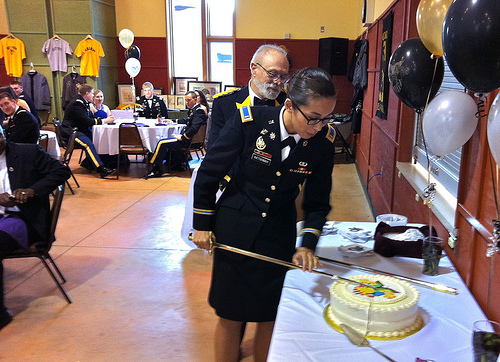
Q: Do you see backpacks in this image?
A: Yes, there is a backpack.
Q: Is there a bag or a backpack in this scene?
A: Yes, there is a backpack.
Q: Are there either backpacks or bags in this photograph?
A: Yes, there is a backpack.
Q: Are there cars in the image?
A: No, there are no cars.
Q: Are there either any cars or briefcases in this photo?
A: No, there are no cars or briefcases.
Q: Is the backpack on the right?
A: Yes, the backpack is on the right of the image.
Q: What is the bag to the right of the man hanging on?
A: The backpack is hanging on the wall.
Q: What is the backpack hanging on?
A: The backpack is hanging on the wall.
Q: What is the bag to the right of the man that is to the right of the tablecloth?
A: The bag is a backpack.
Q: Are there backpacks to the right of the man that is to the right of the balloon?
A: Yes, there is a backpack to the right of the man.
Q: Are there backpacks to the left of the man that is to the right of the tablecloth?
A: No, the backpack is to the right of the man.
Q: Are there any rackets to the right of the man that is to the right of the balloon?
A: No, there is a backpack to the right of the man.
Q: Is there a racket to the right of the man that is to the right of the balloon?
A: No, there is a backpack to the right of the man.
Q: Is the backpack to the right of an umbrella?
A: No, the backpack is to the right of the man.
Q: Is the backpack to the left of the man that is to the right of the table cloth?
A: No, the backpack is to the right of the man.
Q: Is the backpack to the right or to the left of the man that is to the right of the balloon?
A: The backpack is to the right of the man.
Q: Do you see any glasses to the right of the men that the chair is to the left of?
A: Yes, there are glasses to the right of the men.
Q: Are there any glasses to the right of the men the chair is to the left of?
A: Yes, there are glasses to the right of the men.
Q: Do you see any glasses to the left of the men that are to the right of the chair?
A: No, the glasses are to the right of the men.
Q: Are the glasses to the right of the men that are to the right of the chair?
A: Yes, the glasses are to the right of the men.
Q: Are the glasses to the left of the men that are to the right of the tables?
A: No, the glasses are to the right of the men.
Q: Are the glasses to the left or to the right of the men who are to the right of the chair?
A: The glasses are to the right of the men.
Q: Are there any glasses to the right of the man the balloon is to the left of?
A: Yes, there are glasses to the right of the man.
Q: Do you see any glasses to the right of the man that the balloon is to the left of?
A: Yes, there are glasses to the right of the man.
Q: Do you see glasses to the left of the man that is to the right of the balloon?
A: No, the glasses are to the right of the man.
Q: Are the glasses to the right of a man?
A: Yes, the glasses are to the right of a man.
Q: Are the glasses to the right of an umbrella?
A: No, the glasses are to the right of a man.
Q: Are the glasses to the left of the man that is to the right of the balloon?
A: No, the glasses are to the right of the man.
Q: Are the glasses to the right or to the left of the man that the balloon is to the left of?
A: The glasses are to the right of the man.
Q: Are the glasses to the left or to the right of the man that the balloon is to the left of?
A: The glasses are to the right of the man.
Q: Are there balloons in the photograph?
A: Yes, there is a balloon.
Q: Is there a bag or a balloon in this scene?
A: Yes, there is a balloon.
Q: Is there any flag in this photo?
A: No, there are no flags.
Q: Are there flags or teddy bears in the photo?
A: No, there are no flags or teddy bears.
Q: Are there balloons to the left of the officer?
A: Yes, there is a balloon to the left of the officer.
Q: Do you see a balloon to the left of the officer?
A: Yes, there is a balloon to the left of the officer.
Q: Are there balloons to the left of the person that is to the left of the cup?
A: Yes, there is a balloon to the left of the officer.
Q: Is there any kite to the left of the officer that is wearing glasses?
A: No, there is a balloon to the left of the officer.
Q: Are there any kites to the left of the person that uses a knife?
A: No, there is a balloon to the left of the officer.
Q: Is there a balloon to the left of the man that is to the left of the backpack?
A: Yes, there is a balloon to the left of the man.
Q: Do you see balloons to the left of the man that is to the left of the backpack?
A: Yes, there is a balloon to the left of the man.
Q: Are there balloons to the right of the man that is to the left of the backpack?
A: No, the balloon is to the left of the man.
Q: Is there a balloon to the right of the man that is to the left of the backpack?
A: No, the balloon is to the left of the man.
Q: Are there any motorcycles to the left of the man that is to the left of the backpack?
A: No, there is a balloon to the left of the man.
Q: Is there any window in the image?
A: Yes, there is a window.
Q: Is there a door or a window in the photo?
A: Yes, there is a window.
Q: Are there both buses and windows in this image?
A: No, there is a window but no buses.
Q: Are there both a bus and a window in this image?
A: No, there is a window but no buses.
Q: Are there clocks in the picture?
A: No, there are no clocks.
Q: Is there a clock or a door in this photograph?
A: No, there are no clocks or doors.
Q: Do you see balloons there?
A: Yes, there is a balloon.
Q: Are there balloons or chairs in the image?
A: Yes, there is a balloon.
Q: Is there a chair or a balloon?
A: Yes, there is a balloon.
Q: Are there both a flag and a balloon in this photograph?
A: No, there is a balloon but no flags.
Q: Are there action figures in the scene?
A: No, there are no action figures.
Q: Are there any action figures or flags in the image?
A: No, there are no action figures or flags.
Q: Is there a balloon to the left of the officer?
A: Yes, there is a balloon to the left of the officer.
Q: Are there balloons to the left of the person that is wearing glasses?
A: Yes, there is a balloon to the left of the officer.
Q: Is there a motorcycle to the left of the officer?
A: No, there is a balloon to the left of the officer.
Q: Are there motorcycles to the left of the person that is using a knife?
A: No, there is a balloon to the left of the officer.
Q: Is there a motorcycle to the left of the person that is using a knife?
A: No, there is a balloon to the left of the officer.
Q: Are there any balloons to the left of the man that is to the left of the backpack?
A: Yes, there is a balloon to the left of the man.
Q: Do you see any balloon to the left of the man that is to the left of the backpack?
A: Yes, there is a balloon to the left of the man.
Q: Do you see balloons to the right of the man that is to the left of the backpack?
A: No, the balloon is to the left of the man.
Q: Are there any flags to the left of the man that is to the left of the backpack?
A: No, there is a balloon to the left of the man.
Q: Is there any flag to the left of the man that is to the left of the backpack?
A: No, there is a balloon to the left of the man.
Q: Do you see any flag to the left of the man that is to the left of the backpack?
A: No, there is a balloon to the left of the man.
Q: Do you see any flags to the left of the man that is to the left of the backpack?
A: No, there is a balloon to the left of the man.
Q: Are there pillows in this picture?
A: No, there are no pillows.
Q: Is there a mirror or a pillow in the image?
A: No, there are no pillows or mirrors.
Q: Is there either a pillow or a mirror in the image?
A: No, there are no pillows or mirrors.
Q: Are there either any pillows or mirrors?
A: No, there are no pillows or mirrors.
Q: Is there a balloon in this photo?
A: Yes, there is a balloon.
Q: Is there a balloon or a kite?
A: Yes, there is a balloon.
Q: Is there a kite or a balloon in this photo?
A: Yes, there is a balloon.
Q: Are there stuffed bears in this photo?
A: No, there are no stuffed bears.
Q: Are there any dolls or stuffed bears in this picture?
A: No, there are no stuffed bears or dolls.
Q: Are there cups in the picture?
A: Yes, there is a cup.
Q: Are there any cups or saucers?
A: Yes, there is a cup.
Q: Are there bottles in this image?
A: No, there are no bottles.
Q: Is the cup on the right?
A: Yes, the cup is on the right of the image.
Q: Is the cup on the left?
A: No, the cup is on the right of the image.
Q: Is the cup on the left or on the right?
A: The cup is on the right of the image.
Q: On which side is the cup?
A: The cup is on the right of the image.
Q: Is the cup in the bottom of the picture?
A: Yes, the cup is in the bottom of the image.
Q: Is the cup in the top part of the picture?
A: No, the cup is in the bottom of the image.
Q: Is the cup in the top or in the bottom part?
A: The cup is in the bottom of the image.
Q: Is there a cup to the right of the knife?
A: Yes, there is a cup to the right of the knife.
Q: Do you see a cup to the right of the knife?
A: Yes, there is a cup to the right of the knife.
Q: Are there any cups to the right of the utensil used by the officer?
A: Yes, there is a cup to the right of the knife.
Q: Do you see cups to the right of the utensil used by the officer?
A: Yes, there is a cup to the right of the knife.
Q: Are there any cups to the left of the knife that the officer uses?
A: No, the cup is to the right of the knife.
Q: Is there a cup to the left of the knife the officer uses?
A: No, the cup is to the right of the knife.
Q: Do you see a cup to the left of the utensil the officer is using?
A: No, the cup is to the right of the knife.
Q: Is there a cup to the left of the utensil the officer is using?
A: No, the cup is to the right of the knife.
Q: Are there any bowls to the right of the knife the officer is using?
A: No, there is a cup to the right of the knife.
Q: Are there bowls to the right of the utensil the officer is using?
A: No, there is a cup to the right of the knife.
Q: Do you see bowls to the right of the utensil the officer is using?
A: No, there is a cup to the right of the knife.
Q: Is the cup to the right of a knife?
A: Yes, the cup is to the right of a knife.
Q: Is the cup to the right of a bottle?
A: No, the cup is to the right of a knife.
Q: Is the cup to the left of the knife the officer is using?
A: No, the cup is to the right of the knife.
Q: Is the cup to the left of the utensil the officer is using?
A: No, the cup is to the right of the knife.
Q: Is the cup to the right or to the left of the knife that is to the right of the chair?
A: The cup is to the right of the knife.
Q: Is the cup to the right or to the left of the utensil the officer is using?
A: The cup is to the right of the knife.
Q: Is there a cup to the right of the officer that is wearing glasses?
A: Yes, there is a cup to the right of the officer.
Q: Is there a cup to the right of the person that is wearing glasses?
A: Yes, there is a cup to the right of the officer.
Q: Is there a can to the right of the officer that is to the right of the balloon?
A: No, there is a cup to the right of the officer.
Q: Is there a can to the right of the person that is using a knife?
A: No, there is a cup to the right of the officer.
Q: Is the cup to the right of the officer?
A: Yes, the cup is to the right of the officer.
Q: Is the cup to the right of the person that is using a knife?
A: Yes, the cup is to the right of the officer.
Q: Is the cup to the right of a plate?
A: No, the cup is to the right of the officer.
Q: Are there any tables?
A: Yes, there is a table.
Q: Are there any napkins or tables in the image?
A: Yes, there is a table.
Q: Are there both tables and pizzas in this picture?
A: No, there is a table but no pizzas.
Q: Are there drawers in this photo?
A: No, there are no drawers.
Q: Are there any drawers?
A: No, there are no drawers.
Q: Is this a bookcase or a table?
A: This is a table.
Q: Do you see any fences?
A: No, there are no fences.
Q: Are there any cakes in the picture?
A: Yes, there is a cake.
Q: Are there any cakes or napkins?
A: Yes, there is a cake.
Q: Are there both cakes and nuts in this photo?
A: No, there is a cake but no nuts.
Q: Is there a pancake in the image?
A: No, there are no pancakes.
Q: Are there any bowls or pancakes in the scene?
A: No, there are no pancakes or bowls.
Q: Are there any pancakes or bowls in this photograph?
A: No, there are no pancakes or bowls.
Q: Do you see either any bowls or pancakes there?
A: No, there are no pancakes or bowls.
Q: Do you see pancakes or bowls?
A: No, there are no pancakes or bowls.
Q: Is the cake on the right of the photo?
A: Yes, the cake is on the right of the image.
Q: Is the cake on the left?
A: No, the cake is on the right of the image.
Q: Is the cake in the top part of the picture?
A: No, the cake is in the bottom of the image.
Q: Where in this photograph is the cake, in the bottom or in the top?
A: The cake is in the bottom of the image.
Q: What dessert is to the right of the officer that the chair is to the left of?
A: The dessert is a cake.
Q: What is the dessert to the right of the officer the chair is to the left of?
A: The dessert is a cake.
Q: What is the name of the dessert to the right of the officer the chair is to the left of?
A: The dessert is a cake.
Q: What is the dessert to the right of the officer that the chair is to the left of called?
A: The dessert is a cake.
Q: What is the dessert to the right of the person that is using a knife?
A: The dessert is a cake.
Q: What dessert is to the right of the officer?
A: The dessert is a cake.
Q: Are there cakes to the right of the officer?
A: Yes, there is a cake to the right of the officer.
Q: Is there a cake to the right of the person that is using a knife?
A: Yes, there is a cake to the right of the officer.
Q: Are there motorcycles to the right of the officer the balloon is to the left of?
A: No, there is a cake to the right of the officer.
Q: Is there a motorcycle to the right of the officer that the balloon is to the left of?
A: No, there is a cake to the right of the officer.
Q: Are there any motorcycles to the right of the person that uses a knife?
A: No, there is a cake to the right of the officer.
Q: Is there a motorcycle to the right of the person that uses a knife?
A: No, there is a cake to the right of the officer.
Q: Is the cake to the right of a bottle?
A: No, the cake is to the right of an officer.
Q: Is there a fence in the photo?
A: No, there are no fences.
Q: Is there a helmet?
A: No, there are no helmets.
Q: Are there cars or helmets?
A: No, there are no helmets or cars.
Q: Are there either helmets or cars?
A: No, there are no helmets or cars.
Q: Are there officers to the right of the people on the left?
A: Yes, there is an officer to the right of the people.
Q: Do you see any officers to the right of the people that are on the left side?
A: Yes, there is an officer to the right of the people.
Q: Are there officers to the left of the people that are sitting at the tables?
A: No, the officer is to the right of the people.